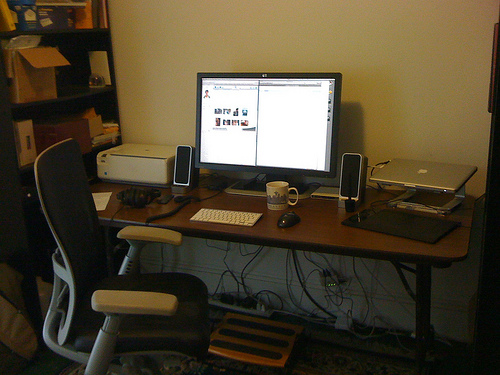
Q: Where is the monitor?
A: On top of the desk.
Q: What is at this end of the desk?
A: A keypad.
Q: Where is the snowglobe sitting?
A: Second shelf of the bookcase.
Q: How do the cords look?
A: Tangled.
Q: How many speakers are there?
A: Two.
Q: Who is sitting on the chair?
A: No one.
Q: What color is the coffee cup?
A: Ivory.